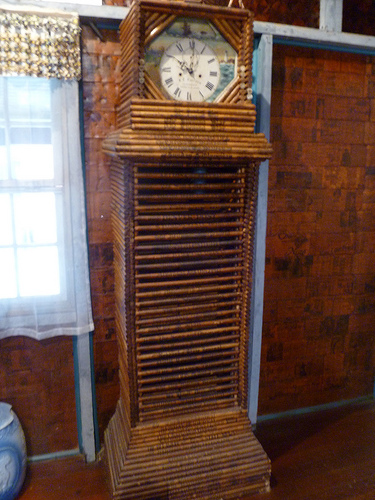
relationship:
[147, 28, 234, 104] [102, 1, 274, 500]
clock on clock holder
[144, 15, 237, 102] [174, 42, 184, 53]
clock has roman numerals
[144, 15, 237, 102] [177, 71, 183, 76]
clock has key hole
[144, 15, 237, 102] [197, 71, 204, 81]
clock has key hole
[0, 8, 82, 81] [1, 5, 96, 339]
baseball cap on curtain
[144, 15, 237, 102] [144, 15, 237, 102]
clock of clock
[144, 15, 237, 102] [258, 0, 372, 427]
clock against wall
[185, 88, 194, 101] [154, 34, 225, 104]
roman numeral on clock face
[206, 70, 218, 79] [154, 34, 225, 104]
roman numeral on clock face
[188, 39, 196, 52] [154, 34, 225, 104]
roman numeral on clock face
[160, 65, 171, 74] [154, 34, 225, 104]
roman numeral on clock face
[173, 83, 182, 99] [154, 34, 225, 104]
roman numeral on clock face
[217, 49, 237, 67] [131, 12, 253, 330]
light house on clock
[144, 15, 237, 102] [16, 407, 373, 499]
clock from floor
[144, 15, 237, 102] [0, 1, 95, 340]
clock past curtain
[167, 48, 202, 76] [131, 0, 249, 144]
hands on clock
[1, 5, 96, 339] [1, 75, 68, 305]
curtain over window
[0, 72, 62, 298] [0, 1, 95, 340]
pane of curtain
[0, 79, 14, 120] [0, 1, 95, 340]
pane of curtain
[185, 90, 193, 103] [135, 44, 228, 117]
vi on face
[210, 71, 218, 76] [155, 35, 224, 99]
roman numeral on clock face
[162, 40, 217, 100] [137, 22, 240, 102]
numerals on clock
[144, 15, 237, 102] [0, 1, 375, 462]
clock against brown wall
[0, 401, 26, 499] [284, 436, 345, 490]
pot on floor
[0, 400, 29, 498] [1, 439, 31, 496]
pot with designs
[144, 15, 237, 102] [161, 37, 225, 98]
clock with numerals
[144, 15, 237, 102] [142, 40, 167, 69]
clock with design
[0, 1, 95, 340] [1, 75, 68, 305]
curtain on window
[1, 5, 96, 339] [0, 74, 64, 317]
curtain over window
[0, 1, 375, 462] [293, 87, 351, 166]
brown wall with tiles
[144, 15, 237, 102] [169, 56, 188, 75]
clock has hand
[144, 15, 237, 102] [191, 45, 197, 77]
clock has hand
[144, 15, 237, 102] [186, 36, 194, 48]
clock has numerals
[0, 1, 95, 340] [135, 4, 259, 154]
curtain on left side of clock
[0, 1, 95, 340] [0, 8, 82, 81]
curtain covered with baseball cap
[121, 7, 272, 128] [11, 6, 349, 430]
clock in front of wall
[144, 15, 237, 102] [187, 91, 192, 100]
clock has roman numeral